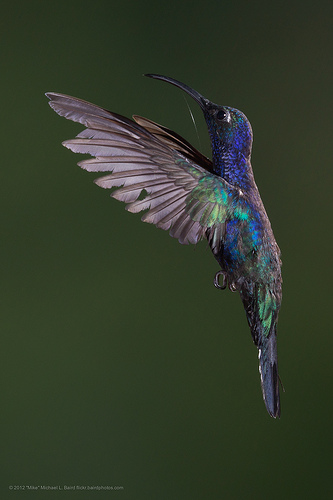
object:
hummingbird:
[43, 72, 286, 419]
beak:
[143, 72, 204, 110]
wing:
[43, 90, 229, 245]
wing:
[130, 115, 217, 183]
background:
[1, 0, 332, 499]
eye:
[215, 110, 227, 126]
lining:
[214, 107, 231, 125]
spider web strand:
[178, 86, 206, 172]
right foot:
[228, 279, 239, 292]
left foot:
[213, 270, 228, 292]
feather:
[212, 187, 226, 207]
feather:
[204, 203, 218, 228]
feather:
[249, 224, 261, 246]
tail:
[257, 321, 286, 420]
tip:
[256, 356, 285, 420]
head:
[207, 97, 252, 159]